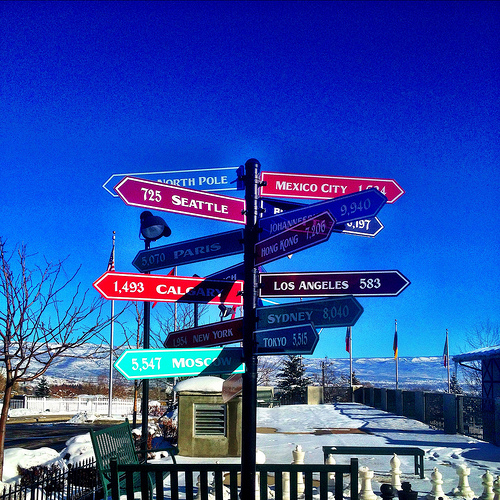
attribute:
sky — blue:
[157, 21, 354, 133]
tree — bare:
[15, 254, 79, 353]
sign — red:
[116, 181, 241, 239]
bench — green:
[88, 423, 156, 463]